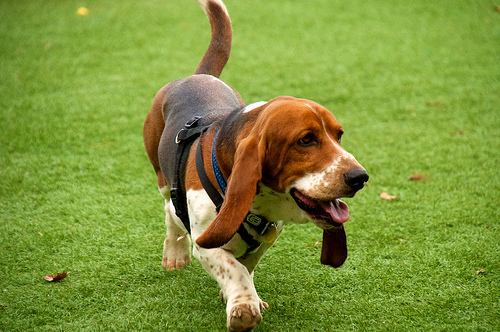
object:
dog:
[140, 0, 368, 332]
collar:
[208, 122, 273, 235]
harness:
[171, 115, 261, 250]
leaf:
[43, 271, 72, 282]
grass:
[0, 0, 498, 332]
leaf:
[378, 192, 399, 200]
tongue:
[319, 197, 350, 224]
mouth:
[288, 186, 354, 231]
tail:
[191, 0, 233, 80]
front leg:
[189, 192, 269, 330]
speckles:
[227, 258, 237, 268]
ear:
[195, 135, 262, 249]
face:
[286, 111, 342, 189]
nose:
[343, 168, 371, 192]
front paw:
[222, 298, 270, 331]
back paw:
[159, 237, 193, 270]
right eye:
[295, 129, 320, 147]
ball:
[74, 5, 90, 15]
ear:
[318, 218, 349, 268]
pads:
[232, 314, 256, 329]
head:
[194, 94, 368, 270]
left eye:
[335, 127, 344, 142]